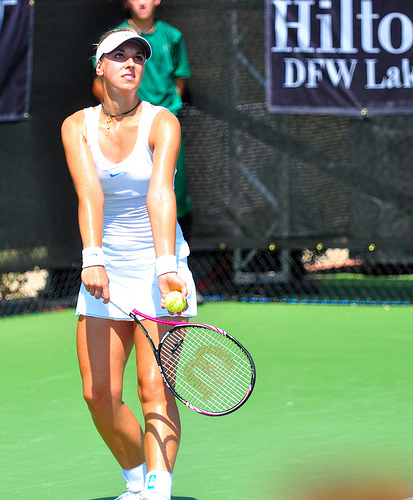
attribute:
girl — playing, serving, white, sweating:
[60, 48, 236, 392]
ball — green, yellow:
[157, 281, 200, 318]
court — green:
[290, 307, 370, 417]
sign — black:
[260, 13, 409, 104]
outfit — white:
[79, 143, 168, 274]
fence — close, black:
[263, 143, 336, 216]